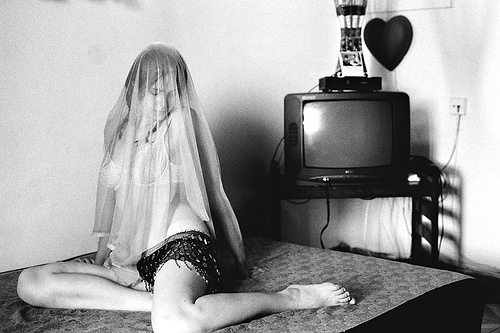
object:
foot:
[281, 280, 356, 310]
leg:
[16, 260, 153, 313]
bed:
[0, 235, 484, 333]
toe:
[340, 297, 357, 306]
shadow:
[407, 166, 465, 269]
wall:
[278, 0, 499, 304]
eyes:
[147, 91, 159, 100]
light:
[298, 100, 329, 150]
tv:
[283, 91, 409, 190]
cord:
[318, 179, 333, 248]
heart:
[360, 15, 412, 72]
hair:
[114, 40, 186, 140]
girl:
[15, 41, 357, 332]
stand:
[268, 156, 443, 268]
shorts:
[134, 229, 223, 294]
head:
[126, 41, 185, 124]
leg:
[143, 240, 288, 333]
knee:
[14, 260, 61, 306]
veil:
[89, 42, 254, 288]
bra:
[101, 110, 183, 193]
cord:
[437, 115, 465, 171]